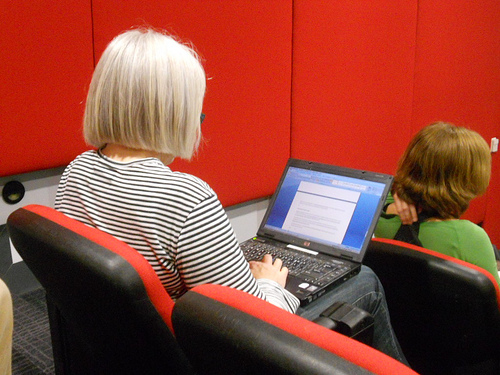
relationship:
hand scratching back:
[391, 191, 424, 223] [375, 191, 499, 284]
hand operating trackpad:
[248, 251, 288, 287] [249, 255, 293, 286]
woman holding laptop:
[54, 26, 413, 367] [238, 156, 396, 308]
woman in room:
[54, 26, 413, 367] [1, 0, 500, 374]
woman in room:
[373, 121, 499, 292] [1, 0, 500, 374]